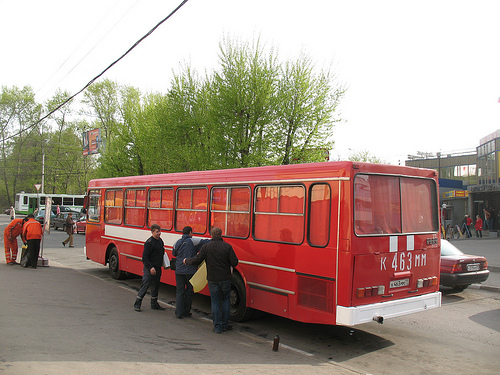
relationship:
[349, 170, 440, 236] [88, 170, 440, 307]
rear window of bus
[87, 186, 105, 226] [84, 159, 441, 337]
window of bus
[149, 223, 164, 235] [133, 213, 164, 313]
head of man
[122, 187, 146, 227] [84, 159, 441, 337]
window of bus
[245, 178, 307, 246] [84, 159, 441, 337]
window of bus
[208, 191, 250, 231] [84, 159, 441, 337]
window of bus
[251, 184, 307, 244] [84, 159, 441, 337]
window on bus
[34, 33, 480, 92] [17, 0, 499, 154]
clouds in sky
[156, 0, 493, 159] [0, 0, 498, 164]
cloud in blue sky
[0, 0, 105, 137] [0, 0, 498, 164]
cloud in blue sky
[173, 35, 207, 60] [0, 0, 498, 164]
white clouds are in blue sky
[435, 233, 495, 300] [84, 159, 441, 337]
car next to bus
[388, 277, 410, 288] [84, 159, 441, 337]
license plate on bus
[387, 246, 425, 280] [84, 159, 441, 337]
numbers on bus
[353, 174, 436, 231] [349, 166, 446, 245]
curtains on rear window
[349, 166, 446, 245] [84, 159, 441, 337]
rear window of bus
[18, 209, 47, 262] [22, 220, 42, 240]
man wearing jacket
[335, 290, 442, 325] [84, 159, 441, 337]
white bumper on bus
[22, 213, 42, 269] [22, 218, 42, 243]
man wearing jacket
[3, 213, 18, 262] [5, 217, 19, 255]
man wearing orange clothes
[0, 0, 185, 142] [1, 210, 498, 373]
line over street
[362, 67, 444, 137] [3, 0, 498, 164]
white clouds in blue sky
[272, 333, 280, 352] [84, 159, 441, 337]
bottle near bus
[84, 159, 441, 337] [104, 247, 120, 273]
bus has tire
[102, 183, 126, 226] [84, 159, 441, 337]
window on bus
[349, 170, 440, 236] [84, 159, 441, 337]
rear window on bus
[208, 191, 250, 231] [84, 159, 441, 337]
window on bus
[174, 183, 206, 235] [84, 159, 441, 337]
window on bus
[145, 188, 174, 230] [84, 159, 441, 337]
window bus on bus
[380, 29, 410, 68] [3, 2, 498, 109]
cloud in sky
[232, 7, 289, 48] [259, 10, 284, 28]
cloud in sky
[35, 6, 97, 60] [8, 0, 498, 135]
clouds in sky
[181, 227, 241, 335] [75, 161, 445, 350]
man near red bus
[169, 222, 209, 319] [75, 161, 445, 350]
man near red bus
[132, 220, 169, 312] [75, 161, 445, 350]
man near red bus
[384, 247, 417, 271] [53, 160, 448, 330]
number 463 on bus